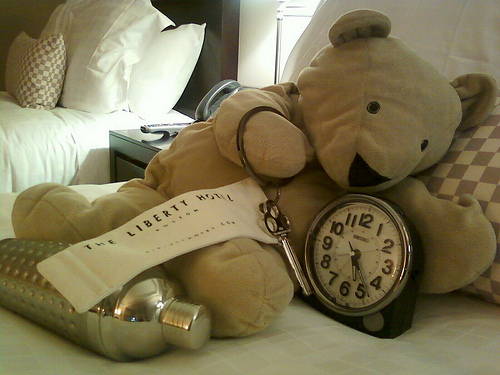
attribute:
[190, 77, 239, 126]
handset — silver, phone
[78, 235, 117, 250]
word — black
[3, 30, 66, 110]
pillow — checkered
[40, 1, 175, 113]
pillow — white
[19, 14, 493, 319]
bear — ted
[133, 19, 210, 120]
pillow — white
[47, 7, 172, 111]
pillow — white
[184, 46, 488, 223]
bear — ted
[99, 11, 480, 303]
teddy bear — leg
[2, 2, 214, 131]
pillows — standing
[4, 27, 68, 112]
pillow — decorative, bed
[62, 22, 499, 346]
bear — stuffed, teddy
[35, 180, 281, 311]
banner — white, small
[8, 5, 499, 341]
teddy bear — brown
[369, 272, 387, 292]
number — black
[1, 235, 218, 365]
flask — silver, horizontal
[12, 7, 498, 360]
bear — ted, mouth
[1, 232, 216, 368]
bottle — silver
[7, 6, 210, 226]
bedding — white